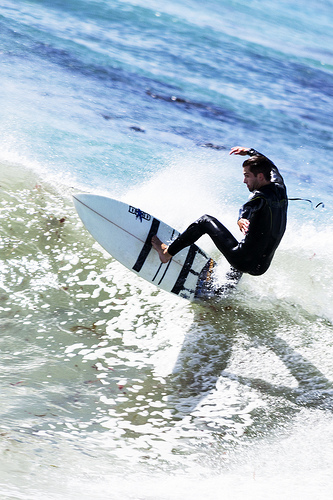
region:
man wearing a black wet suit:
[148, 145, 288, 276]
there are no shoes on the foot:
[149, 234, 172, 263]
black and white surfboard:
[70, 192, 223, 308]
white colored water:
[2, 179, 332, 499]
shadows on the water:
[120, 301, 332, 426]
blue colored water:
[0, 0, 332, 229]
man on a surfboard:
[70, 143, 288, 304]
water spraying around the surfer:
[0, 149, 326, 238]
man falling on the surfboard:
[72, 146, 288, 301]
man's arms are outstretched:
[150, 145, 287, 299]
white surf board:
[83, 200, 191, 290]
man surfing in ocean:
[114, 138, 287, 308]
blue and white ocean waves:
[112, 376, 162, 422]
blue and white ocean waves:
[192, 395, 238, 429]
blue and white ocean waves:
[29, 296, 74, 345]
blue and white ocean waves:
[77, 102, 116, 131]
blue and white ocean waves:
[165, 123, 207, 175]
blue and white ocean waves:
[284, 322, 315, 366]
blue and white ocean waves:
[51, 66, 84, 102]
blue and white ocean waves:
[137, 98, 186, 162]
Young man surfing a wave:
[62, 118, 332, 316]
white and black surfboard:
[72, 189, 234, 313]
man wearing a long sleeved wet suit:
[154, 141, 288, 277]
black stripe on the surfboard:
[132, 216, 163, 274]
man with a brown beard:
[246, 177, 263, 193]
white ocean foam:
[113, 292, 287, 408]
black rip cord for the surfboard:
[288, 193, 327, 211]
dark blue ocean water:
[41, 40, 171, 104]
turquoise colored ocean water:
[219, 28, 310, 65]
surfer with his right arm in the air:
[230, 140, 301, 247]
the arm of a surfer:
[236, 194, 260, 231]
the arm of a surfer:
[230, 141, 283, 183]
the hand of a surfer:
[229, 144, 247, 157]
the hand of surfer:
[236, 218, 249, 233]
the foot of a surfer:
[150, 234, 169, 257]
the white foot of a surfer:
[206, 258, 216, 283]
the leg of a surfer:
[168, 213, 236, 263]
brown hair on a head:
[242, 156, 268, 177]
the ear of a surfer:
[256, 171, 265, 182]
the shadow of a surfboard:
[166, 296, 233, 416]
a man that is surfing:
[69, 126, 332, 351]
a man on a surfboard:
[77, 118, 323, 295]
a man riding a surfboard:
[67, 66, 323, 285]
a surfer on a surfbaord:
[64, 98, 321, 351]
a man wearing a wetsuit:
[152, 131, 316, 300]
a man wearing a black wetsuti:
[174, 150, 332, 313]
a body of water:
[28, 108, 330, 399]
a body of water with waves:
[20, 106, 329, 437]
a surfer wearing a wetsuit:
[69, 127, 305, 332]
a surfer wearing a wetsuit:
[138, 169, 321, 319]